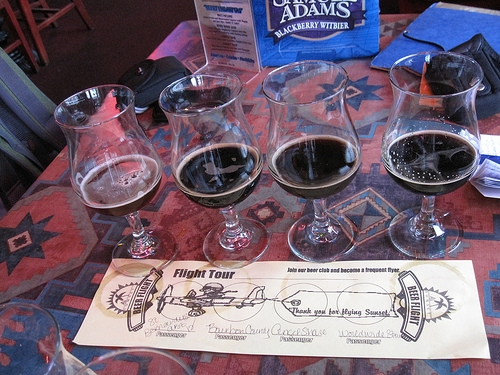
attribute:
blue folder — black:
[367, 0, 497, 80]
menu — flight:
[72, 257, 492, 358]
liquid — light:
[384, 128, 476, 196]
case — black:
[109, 58, 235, 119]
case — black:
[398, 5, 497, 108]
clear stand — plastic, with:
[195, 60, 255, 80]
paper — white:
[72, 259, 490, 358]